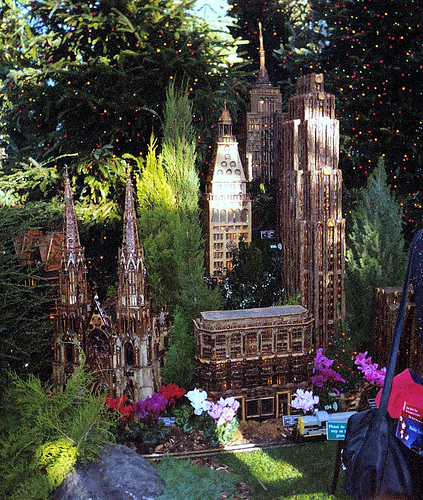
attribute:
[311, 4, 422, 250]
beads — colorful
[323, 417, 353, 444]
sign — green, white, model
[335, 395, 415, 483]
bag — black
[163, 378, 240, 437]
flowers — white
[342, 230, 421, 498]
purse — blue, woman's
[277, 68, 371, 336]
building — tall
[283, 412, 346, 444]
train — gray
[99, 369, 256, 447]
flowers — purple, pink, white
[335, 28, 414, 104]
lights — multi-colored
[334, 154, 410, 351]
tree — evergreen, green, tall, model size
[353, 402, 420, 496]
bag — black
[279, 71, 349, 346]
building — white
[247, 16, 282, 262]
building — white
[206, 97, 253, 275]
building — white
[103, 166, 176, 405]
building — white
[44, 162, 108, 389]
building — white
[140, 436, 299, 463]
track — gray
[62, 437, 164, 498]
rock — grey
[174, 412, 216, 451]
leaves — green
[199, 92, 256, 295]
building — model